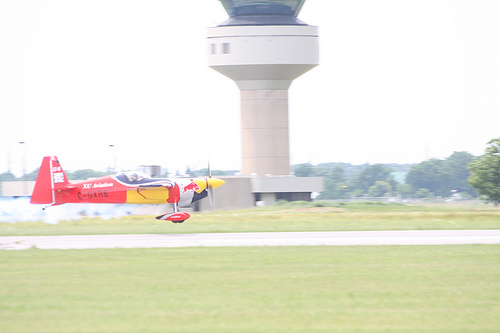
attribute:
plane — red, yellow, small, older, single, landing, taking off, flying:
[30, 155, 225, 223]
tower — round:
[203, 1, 325, 205]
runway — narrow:
[1, 231, 499, 251]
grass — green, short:
[1, 200, 497, 333]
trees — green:
[293, 138, 499, 204]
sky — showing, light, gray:
[0, 0, 499, 179]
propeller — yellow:
[205, 160, 223, 204]